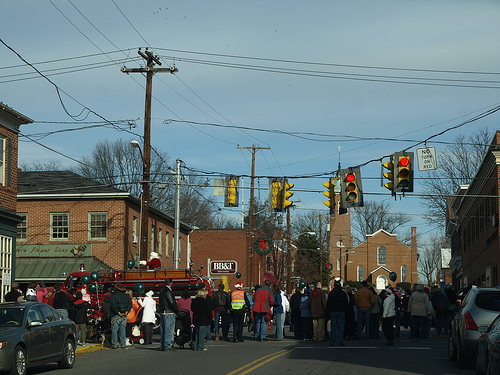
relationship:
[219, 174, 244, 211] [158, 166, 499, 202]
lights on wires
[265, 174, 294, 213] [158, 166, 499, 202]
lights on wires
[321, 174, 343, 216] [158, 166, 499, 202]
lights on wires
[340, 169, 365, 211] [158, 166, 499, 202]
lights on wires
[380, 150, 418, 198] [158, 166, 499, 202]
lights on wires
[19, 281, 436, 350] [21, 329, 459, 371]
people on street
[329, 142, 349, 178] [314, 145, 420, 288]
spire on church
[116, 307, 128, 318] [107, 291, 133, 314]
hands behind back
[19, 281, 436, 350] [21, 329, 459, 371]
people in street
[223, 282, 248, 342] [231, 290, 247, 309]
man wearing vest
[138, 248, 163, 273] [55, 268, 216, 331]
santa on firetruck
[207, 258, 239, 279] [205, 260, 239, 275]
sign for bank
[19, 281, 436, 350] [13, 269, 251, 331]
people watching parade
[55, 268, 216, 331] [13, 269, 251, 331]
firetruck in parade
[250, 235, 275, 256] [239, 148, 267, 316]
wreath on pole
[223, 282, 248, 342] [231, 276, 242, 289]
policeman wearing hat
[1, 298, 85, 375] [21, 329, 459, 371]
vehicle on street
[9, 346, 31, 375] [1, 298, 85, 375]
wheel of vehicle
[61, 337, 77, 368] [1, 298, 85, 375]
wheel of vehicle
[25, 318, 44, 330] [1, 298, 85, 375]
mirror on vehicle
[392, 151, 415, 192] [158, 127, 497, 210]
lights on cable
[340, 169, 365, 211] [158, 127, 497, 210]
light on cable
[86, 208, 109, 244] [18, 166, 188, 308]
window on building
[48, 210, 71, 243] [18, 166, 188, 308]
window on building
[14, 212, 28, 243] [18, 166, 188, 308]
window on building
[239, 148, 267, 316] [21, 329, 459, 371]
pole near street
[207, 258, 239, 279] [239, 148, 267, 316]
sign on pole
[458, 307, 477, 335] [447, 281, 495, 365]
light on vehicle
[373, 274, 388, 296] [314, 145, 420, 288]
door on church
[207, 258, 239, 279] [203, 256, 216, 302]
sign on post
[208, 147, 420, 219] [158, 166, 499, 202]
group on wires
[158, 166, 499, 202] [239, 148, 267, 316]
wires on pole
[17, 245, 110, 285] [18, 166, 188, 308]
awning on building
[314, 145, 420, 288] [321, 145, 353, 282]
church has steeple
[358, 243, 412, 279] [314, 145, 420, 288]
windows on church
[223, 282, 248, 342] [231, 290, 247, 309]
person wearing vest